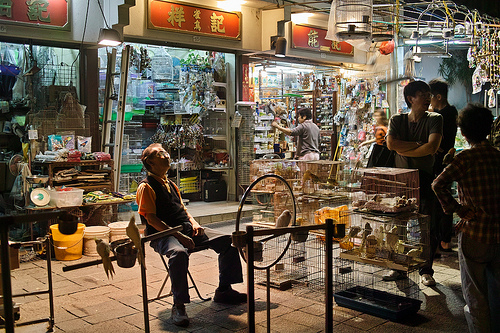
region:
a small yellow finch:
[126, 211, 152, 273]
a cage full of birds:
[336, 215, 433, 268]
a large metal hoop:
[237, 169, 298, 269]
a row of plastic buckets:
[43, 215, 140, 264]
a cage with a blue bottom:
[333, 257, 428, 320]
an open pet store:
[102, 48, 238, 208]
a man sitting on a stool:
[143, 142, 251, 327]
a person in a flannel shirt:
[429, 99, 499, 329]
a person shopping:
[266, 106, 330, 198]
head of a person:
[133, 132, 188, 177]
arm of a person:
[145, 210, 183, 247]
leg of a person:
[158, 244, 200, 299]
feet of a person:
[158, 299, 203, 325]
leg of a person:
[216, 225, 271, 287]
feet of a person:
[212, 282, 268, 304]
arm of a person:
[385, 128, 436, 161]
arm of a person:
[414, 116, 451, 163]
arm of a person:
[265, 113, 297, 150]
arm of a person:
[428, 162, 473, 219]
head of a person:
[125, 131, 187, 181]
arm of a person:
[137, 201, 174, 249]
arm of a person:
[180, 198, 205, 219]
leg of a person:
[160, 252, 196, 326]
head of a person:
[388, 65, 457, 115]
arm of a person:
[390, 127, 422, 154]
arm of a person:
[405, 134, 437, 159]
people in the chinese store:
[10, 8, 498, 324]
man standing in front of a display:
[272, 100, 327, 158]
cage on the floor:
[338, 255, 418, 316]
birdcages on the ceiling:
[332, 6, 392, 42]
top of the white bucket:
[85, 228, 107, 238]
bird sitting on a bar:
[91, 235, 117, 280]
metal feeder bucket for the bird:
[110, 214, 146, 270]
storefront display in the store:
[129, 52, 225, 139]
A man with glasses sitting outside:
[137, 142, 251, 322]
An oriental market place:
[1, 3, 498, 327]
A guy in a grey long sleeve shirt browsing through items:
[276, 110, 320, 192]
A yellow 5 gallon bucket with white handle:
[49, 224, 84, 259]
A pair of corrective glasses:
[145, 148, 167, 158]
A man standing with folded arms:
[386, 83, 438, 178]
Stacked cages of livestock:
[333, 161, 426, 309]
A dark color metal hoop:
[237, 174, 299, 269]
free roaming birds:
[93, 214, 148, 278]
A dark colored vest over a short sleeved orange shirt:
[136, 178, 190, 228]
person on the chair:
[98, 128, 248, 250]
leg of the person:
[148, 240, 204, 326]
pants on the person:
[122, 205, 278, 315]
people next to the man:
[259, 98, 494, 265]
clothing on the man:
[128, 171, 194, 231]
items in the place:
[75, 59, 211, 146]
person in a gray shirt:
[246, 61, 357, 202]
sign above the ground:
[121, 3, 247, 51]